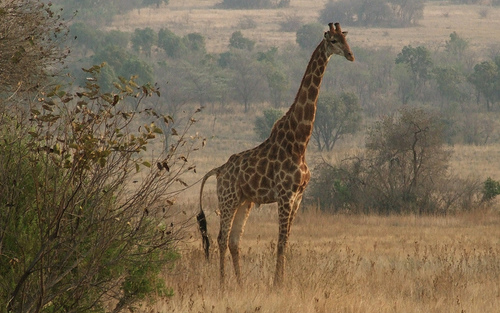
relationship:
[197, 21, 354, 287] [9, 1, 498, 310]
giraffe on field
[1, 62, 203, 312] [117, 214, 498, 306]
bush in field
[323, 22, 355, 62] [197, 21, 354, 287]
giraffe head of giraffe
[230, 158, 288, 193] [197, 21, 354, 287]
spots on giraffe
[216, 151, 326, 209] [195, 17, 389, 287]
lines on giraffe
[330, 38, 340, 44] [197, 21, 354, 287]
eye of giraffe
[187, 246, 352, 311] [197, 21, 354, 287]
grass next to giraffe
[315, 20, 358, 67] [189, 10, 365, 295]
giraffe head of giraffe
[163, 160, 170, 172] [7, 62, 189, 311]
leaf on bush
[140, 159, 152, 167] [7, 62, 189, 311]
leaf on bush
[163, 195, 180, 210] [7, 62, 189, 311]
leaf on bush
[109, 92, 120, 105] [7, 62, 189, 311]
leaf on bush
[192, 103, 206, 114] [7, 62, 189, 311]
leaf on bush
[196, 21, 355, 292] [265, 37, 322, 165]
giraffe has neck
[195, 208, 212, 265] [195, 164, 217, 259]
tuft on tail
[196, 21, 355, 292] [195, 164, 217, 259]
giraffe has tail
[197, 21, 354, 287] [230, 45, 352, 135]
giraffe has neck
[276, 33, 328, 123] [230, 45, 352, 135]
mane on neck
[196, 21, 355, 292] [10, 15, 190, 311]
giraffe standing in foliage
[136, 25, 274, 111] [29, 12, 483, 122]
trees in distance